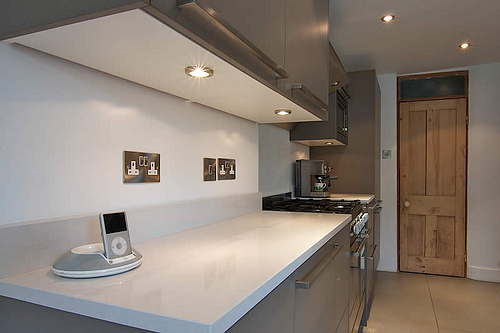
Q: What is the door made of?
A: Wood.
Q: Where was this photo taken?
A: Kitchen.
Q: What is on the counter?
A: An Ipod.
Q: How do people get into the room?
A: Door.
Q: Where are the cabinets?
A: Above counter.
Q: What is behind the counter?
A: Back splash.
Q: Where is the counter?
A: Below cabnits.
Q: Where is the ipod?
A: On a dock.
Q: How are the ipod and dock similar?
A: Both are silver and white.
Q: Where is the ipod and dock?
A: On a kitchen counter.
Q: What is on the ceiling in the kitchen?
A: Recessed lighting.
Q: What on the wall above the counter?
A: An electrical outlet.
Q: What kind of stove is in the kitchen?
A: Gas.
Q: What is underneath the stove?
A: Oven.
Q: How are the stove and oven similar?
A: They are both silver.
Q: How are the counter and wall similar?
A: They are both white.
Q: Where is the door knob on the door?
A: On the left.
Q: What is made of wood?
A: Door.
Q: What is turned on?
A: Lights.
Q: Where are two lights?
A: On the ceiling.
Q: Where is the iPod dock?
A: On the counter.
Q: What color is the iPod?
A: Silver.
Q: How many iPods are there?
A: 1.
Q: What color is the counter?
A: White.